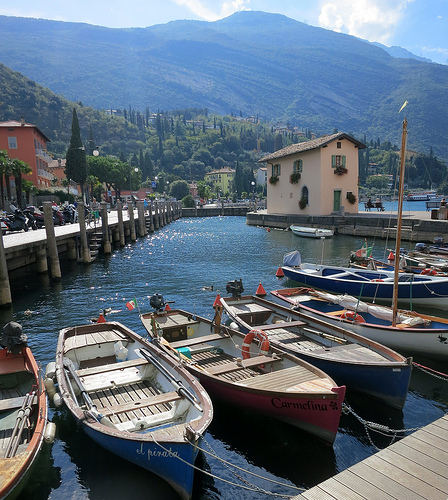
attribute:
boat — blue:
[48, 322, 202, 480]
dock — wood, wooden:
[337, 466, 446, 500]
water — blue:
[180, 217, 259, 281]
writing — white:
[133, 443, 181, 459]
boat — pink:
[143, 304, 342, 434]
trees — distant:
[111, 105, 265, 195]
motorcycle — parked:
[3, 207, 31, 235]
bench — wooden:
[422, 202, 446, 210]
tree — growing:
[64, 109, 88, 183]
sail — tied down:
[305, 289, 399, 323]